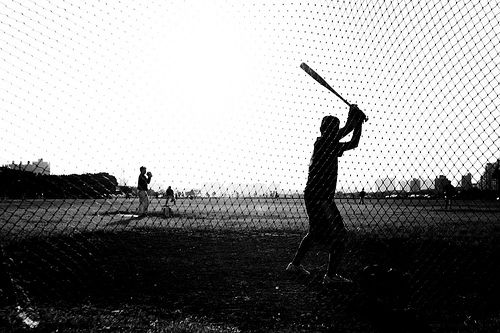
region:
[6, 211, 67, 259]
Small holes in the fence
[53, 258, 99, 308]
Small holes in the fence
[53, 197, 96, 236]
Small holes in the fence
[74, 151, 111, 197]
Small holes in the fence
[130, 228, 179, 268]
Small holes in the fence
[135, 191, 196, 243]
Small holes in the fence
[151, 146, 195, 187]
Small holes in the fence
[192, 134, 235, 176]
Small holes in the fence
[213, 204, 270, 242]
Small holes in the fence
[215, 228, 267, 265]
Small holes in the fence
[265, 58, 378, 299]
kid holding baseball bat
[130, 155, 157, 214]
boy pitching a ball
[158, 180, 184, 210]
baseball player on diamond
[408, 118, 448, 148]
baseball wire fence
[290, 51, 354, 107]
baseball bat in air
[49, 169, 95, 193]
several trees and bushes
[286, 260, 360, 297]
two shoes on baseball diamond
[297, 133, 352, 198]
boy's t shirt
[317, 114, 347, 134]
boy's baseball hat on head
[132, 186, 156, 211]
boy's baseball pants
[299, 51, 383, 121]
baseball bat being held over head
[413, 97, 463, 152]
black chain link fence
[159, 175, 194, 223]
outfielder in a baseball game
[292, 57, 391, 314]
batter at home plate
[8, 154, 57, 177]
tall buildings on the left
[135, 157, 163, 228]
pitcher on the pitchers mound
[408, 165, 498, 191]
tall buildings on the right of photo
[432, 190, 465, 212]
first baseman on first base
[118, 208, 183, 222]
pitchers mound with pitcher on it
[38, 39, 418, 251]
baseball game photo in black and white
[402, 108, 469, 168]
black chain link fencing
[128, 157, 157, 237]
pitcher located on the pitchers mound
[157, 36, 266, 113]
bright glare of the sun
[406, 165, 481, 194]
tall building off in the distance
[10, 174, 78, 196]
cluster of trees on the left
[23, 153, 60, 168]
tall building on left side of photo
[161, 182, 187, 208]
outfielder in baseball game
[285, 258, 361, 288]
white sneakers on batter's feet